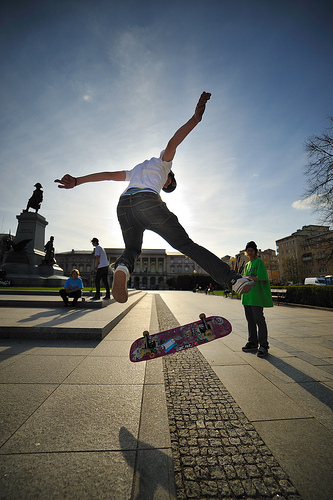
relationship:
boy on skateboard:
[33, 84, 258, 310] [115, 308, 247, 364]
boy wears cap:
[237, 236, 281, 363] [245, 238, 262, 255]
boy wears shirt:
[237, 236, 281, 363] [234, 256, 285, 314]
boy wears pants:
[237, 236, 281, 363] [238, 300, 283, 348]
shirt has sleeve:
[234, 256, 285, 314] [254, 260, 276, 283]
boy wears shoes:
[237, 236, 281, 363] [239, 337, 279, 361]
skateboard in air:
[115, 308, 247, 364] [104, 306, 294, 469]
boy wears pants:
[33, 84, 258, 310] [106, 182, 239, 289]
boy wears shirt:
[33, 84, 258, 310] [116, 145, 178, 198]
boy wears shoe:
[33, 84, 258, 310] [110, 264, 135, 308]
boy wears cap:
[33, 84, 258, 310] [164, 170, 182, 193]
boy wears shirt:
[58, 269, 89, 315] [60, 277, 88, 293]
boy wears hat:
[85, 230, 116, 305] [88, 234, 104, 249]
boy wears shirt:
[85, 230, 116, 305] [91, 244, 116, 273]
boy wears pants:
[85, 230, 116, 305] [94, 265, 110, 304]